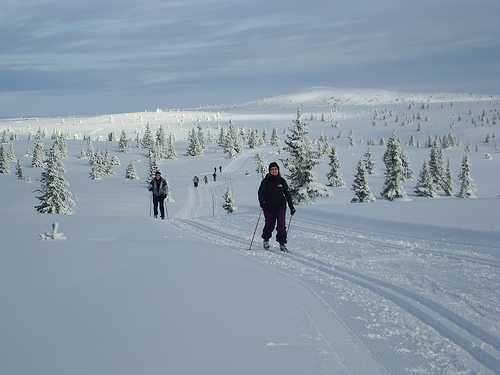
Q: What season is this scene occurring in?
A: Winter.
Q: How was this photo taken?
A: Camera.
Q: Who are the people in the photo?
A: Skiers.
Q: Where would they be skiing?
A: Snow.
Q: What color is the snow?
A: White.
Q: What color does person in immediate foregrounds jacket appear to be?
A: Black.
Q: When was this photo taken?
A: Daytime.